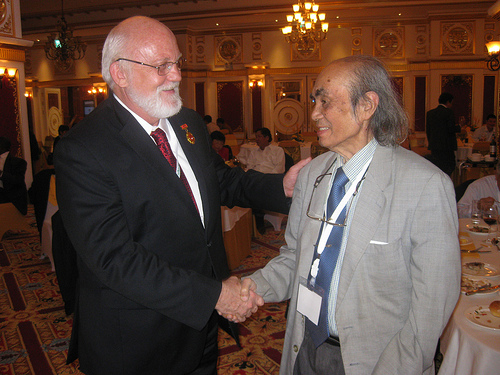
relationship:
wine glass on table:
[483, 205, 496, 240] [455, 239, 495, 364]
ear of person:
[348, 90, 387, 127] [236, 52, 463, 365]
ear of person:
[107, 59, 129, 89] [53, 13, 313, 373]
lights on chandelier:
[278, 24, 298, 39] [273, 2, 334, 60]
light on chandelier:
[286, 15, 295, 22] [274, 0, 328, 55]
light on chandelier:
[291, 4, 301, 11] [274, 0, 328, 55]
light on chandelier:
[295, 15, 302, 20] [274, 0, 328, 55]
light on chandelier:
[313, 5, 319, 12] [274, 0, 328, 55]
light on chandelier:
[322, 22, 329, 30] [274, 0, 328, 55]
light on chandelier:
[310, 0, 318, 11] [274, 0, 334, 67]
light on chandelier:
[307, 11, 314, 21] [274, 0, 334, 67]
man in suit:
[29, 13, 293, 373] [54, 88, 292, 373]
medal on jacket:
[177, 121, 197, 148] [50, 97, 223, 369]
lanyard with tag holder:
[306, 161, 370, 288] [314, 149, 349, 348]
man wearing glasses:
[255, 56, 447, 373] [305, 181, 354, 239]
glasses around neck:
[305, 181, 354, 239] [327, 132, 380, 158]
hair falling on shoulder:
[337, 50, 412, 145] [379, 138, 441, 181]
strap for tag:
[269, 160, 389, 315] [294, 280, 322, 324]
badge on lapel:
[171, 115, 213, 164] [164, 104, 227, 166]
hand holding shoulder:
[266, 153, 323, 197] [295, 143, 344, 185]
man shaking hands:
[20, 9, 303, 362] [201, 259, 269, 330]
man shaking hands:
[255, 56, 447, 373] [201, 259, 269, 330]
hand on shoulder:
[266, 153, 323, 197] [295, 143, 344, 185]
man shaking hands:
[29, 13, 293, 373] [201, 259, 269, 330]